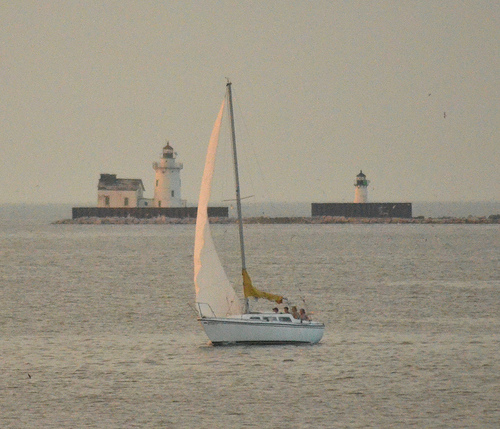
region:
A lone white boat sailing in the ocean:
[179, 72, 348, 379]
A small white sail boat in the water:
[175, 76, 338, 366]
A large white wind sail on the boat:
[188, 92, 227, 331]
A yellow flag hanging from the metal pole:
[240, 270, 285, 305]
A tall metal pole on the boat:
[220, 72, 256, 314]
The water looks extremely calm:
[5, 376, 412, 426]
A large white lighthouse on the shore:
[153, 137, 195, 216]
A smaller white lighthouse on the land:
[351, 165, 374, 208]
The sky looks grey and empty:
[248, 15, 415, 130]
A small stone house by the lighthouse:
[96, 170, 148, 210]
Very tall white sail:
[164, 60, 267, 321]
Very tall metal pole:
[214, 75, 252, 312]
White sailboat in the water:
[182, 53, 345, 357]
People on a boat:
[257, 282, 327, 352]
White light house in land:
[134, 110, 201, 217]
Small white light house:
[340, 166, 389, 210]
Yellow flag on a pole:
[230, 262, 293, 307]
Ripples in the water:
[30, 370, 74, 395]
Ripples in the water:
[101, 388, 171, 425]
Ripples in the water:
[267, 391, 351, 427]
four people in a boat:
[247, 301, 329, 351]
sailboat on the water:
[192, 64, 331, 356]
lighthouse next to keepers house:
[93, 138, 190, 222]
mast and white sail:
[194, 90, 245, 337]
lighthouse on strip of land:
[305, 168, 418, 229]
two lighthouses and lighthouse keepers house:
[65, 131, 417, 248]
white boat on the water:
[192, 298, 328, 360]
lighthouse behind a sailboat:
[194, 74, 418, 359]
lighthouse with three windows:
[148, 133, 187, 221]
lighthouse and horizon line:
[304, 161, 479, 230]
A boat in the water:
[190, 82, 330, 352]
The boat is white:
[172, 81, 339, 337]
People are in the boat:
[265, 305, 315, 325]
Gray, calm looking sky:
[2, 7, 492, 193]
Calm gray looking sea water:
[5, 201, 485, 416]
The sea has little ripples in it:
[5, 200, 495, 420]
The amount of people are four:
[271, 301, 307, 321]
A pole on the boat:
[223, 78, 259, 313]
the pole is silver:
[226, 73, 256, 307]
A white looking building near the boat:
[87, 169, 152, 205]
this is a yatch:
[181, 71, 356, 387]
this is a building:
[75, 78, 234, 265]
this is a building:
[299, 131, 431, 256]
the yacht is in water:
[74, 277, 181, 410]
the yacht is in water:
[361, 326, 449, 413]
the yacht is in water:
[23, 219, 137, 323]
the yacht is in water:
[360, 283, 451, 362]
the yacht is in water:
[89, 346, 186, 417]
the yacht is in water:
[41, 235, 152, 299]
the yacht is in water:
[193, 355, 310, 417]